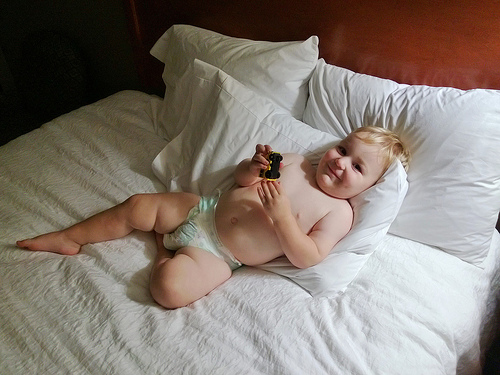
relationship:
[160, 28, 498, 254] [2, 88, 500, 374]
pillow on bed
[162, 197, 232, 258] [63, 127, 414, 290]
diaper on baby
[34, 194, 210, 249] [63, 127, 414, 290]
leg of baby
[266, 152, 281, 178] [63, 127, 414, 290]
toy of baby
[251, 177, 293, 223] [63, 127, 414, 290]
hand of baby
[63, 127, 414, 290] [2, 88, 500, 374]
baby on bed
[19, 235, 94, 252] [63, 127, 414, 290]
foot of baby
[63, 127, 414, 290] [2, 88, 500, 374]
baby in a bed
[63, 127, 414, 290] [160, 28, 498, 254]
baby laying on pillow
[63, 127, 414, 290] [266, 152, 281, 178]
baby holding toy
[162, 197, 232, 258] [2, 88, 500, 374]
diaper on bed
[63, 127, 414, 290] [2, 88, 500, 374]
baby laying on bed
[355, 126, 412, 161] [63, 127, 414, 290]
hair on baby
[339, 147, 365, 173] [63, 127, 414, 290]
eyes of baby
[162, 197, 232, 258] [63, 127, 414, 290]
diaper being worn by baby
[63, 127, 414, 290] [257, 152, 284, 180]
baby holding truck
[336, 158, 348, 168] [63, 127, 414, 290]
nose of baby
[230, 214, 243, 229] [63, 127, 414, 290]
belly button on baby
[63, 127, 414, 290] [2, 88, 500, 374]
baby laying on a bed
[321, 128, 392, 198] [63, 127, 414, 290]
head of baby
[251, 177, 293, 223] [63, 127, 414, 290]
hand on baby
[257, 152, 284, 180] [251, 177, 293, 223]
truck in hand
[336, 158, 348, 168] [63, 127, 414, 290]
nose on baby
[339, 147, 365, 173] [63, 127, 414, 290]
eyes on baby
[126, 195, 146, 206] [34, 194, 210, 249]
knee on leg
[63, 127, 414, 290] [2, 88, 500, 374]
baby laying in a bed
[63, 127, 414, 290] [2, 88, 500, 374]
baby laying in bed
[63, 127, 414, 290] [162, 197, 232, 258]
baby wearing a diaper